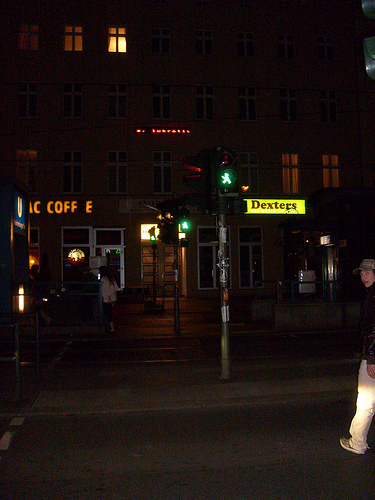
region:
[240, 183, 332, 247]
the sign is yellow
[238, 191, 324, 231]
the sign says Dexters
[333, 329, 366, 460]
the man's pants are white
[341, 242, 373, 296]
the man is wearing a hat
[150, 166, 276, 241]
the lights are green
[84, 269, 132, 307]
the woman's jacket is white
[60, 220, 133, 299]
the windows are white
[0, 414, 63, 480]
the lines are white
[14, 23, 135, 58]
the lights are on in these rooms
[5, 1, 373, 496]
the scene takes place at night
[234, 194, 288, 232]
The yellow light sign is on.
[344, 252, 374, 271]
The guy has on a white cap.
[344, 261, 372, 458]
The guy is crossing the street.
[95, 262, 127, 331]
A lady is walking pass the fence.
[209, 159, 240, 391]
The street light is on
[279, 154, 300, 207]
The curtains are closed in the window.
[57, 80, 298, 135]
The building has windows.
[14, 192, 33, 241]
A blue and white sign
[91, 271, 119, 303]
The lady is wearing a white shirt.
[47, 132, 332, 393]
It is night time outside.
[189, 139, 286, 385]
pedestsrian light on a pole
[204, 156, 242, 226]
pedestrian light green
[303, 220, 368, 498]
person crossing road in photo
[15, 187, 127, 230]
orange sign with one letter out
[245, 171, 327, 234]
yellow sign says Dexters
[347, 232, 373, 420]
person in hat walking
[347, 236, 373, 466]
person in white pants walking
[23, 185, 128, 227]
sign says coffee in orange letters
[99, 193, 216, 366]
door way with green light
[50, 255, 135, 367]
person in front of window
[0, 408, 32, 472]
white painted line on street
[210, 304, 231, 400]
silver pole on street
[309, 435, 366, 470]
white and gray shoe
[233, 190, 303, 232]
sign that says dexters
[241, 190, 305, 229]
yellow and orange sign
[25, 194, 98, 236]
light sign with a letter out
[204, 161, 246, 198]
a green traffic light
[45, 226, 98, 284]
reflection in a window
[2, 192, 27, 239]
blue and white sign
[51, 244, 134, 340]
person walking near a window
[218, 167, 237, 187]
a green street crossing sign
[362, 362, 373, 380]
the hand of a man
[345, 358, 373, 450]
a pair of white pants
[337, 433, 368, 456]
a shoe on the man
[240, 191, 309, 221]
a yellow shop sign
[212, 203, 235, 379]
a gray metal post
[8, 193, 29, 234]
a blue sign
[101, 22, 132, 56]
a window on the building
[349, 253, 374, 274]
a hat on the person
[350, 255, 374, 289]
the head of a man